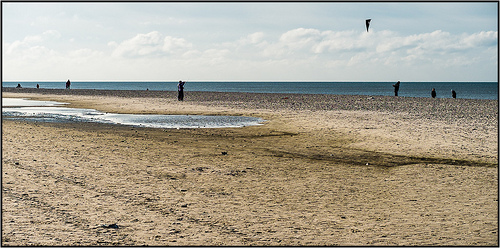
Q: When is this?
A: Daytime.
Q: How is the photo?
A: Clear.